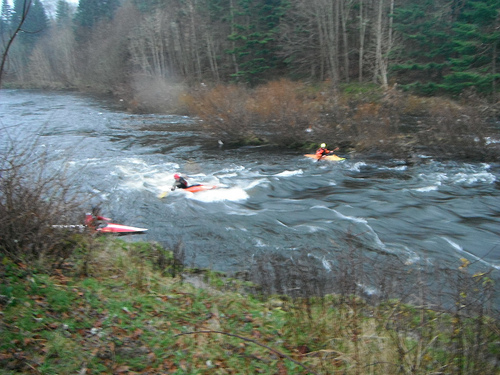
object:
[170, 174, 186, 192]
person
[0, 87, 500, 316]
river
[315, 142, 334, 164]
person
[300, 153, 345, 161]
kayak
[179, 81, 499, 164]
grass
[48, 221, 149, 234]
kayak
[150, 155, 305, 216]
wave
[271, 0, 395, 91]
tree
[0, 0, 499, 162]
woods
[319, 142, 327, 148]
helmet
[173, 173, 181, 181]
helmet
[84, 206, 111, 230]
person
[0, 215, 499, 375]
land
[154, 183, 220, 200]
kayak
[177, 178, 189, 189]
jacket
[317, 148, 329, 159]
jacket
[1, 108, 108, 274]
bush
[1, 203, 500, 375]
shore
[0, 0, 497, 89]
trees